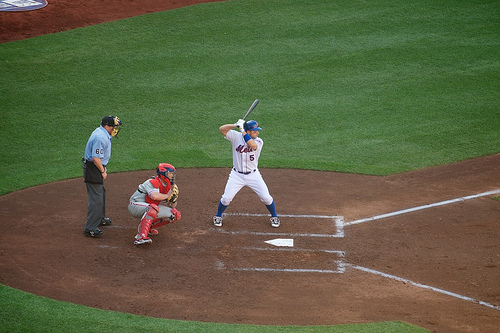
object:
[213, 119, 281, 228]
players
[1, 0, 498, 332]
field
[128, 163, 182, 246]
catcher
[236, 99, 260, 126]
bat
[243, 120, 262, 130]
helmet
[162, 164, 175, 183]
mask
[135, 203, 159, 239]
shin guards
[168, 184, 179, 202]
glove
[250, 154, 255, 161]
number 5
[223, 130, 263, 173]
jersey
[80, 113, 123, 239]
umpire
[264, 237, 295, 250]
home plate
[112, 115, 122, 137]
mask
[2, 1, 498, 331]
grass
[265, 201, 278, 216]
socks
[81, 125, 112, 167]
shirt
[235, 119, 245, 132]
hands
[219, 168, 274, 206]
trousers